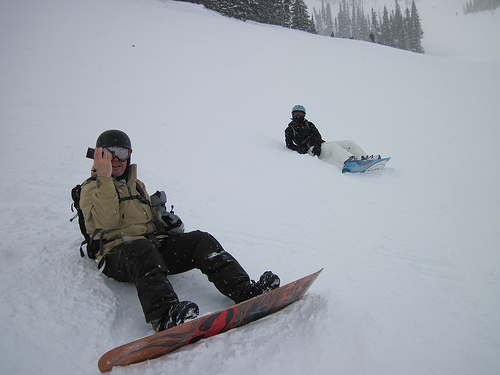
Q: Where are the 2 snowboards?
A: On a hill.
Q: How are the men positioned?
A: Sitting in snow.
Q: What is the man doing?
A: Talking on cell phone.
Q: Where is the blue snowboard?
A: Attached to feet.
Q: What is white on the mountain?
A: Snow.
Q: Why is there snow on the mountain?
A: Winter and cold.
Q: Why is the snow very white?
A: Clean and fresh.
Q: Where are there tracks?
A: In the snow.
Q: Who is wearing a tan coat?
A: Man with cell phone.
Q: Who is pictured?
A: Two people.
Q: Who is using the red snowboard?
A: The person in the front.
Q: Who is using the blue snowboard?
A: The person in the back.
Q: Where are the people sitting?
A: In the snow.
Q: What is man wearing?
A: Black pants.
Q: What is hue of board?
A: Red.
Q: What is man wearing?
A: Brown jacket.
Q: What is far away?
A: Trees.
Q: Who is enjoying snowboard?
A: Two men.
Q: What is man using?
A: Device.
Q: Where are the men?
A: In snow.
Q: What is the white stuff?
A: Snow.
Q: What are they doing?
A: Snowboarding.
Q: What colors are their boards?
A: Red/blue.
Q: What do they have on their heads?
A: Helmets.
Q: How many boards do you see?
A: Two.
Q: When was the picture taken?
A: Daytime.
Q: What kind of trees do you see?
A: Pine.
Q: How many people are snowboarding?
A: Two.